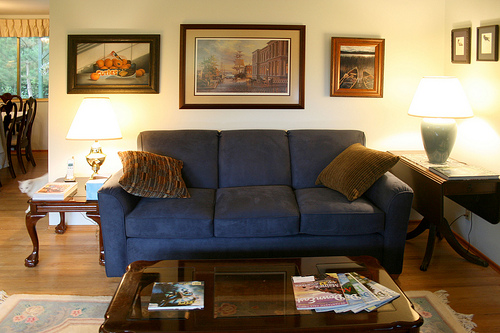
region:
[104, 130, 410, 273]
a dark blue couch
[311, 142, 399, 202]
a large brown pillow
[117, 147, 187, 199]
a large brown pillow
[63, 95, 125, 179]
a lit table lamp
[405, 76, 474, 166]
a lit table lamp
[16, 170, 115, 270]
a wooden end table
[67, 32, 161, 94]
a framed art print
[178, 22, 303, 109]
a framed art print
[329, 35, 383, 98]
a framed art print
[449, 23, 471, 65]
a framed art print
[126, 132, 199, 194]
The pillow on the left side of the sofa.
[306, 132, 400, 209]
The pillow on the right side of the sofa.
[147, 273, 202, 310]
The magazine on the left side of the center table.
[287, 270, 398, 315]
The magazines on the right side of the center table.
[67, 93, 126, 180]
The lamp on the small side table.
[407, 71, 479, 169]
The lamp on the long side table.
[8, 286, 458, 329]
The rug the center table is placed on.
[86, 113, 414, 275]
The blue sofa in the center of the room.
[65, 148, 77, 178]
The bottle of water on the small side table.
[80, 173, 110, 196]
The small blue box on the small side table.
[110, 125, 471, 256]
Blue couch against the wall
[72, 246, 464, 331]
Table with glass top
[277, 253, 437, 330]
Magazines on top of table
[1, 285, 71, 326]
Rug underneath the table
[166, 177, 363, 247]
Cushions on the couch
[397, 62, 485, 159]
Lamp sitting on the table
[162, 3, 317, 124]
Art piece on the wall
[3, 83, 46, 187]
Table surrounded by chairs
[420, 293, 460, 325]
Fringe on the carpet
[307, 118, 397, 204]
Brown pillow on the couch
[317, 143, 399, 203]
Brown throw pillow on a blue couch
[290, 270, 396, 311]
Magazines on the coffee table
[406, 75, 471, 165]
Table lamp on an end table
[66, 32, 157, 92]
Picture of fruit hanging on the wall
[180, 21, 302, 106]
Picture hung on the wall above the couch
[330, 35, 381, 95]
Picture with a wooden frame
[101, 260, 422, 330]
Coffee table in the living room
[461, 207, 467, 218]
Lamp plugged into electrical receptacle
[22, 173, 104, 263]
End table sitting beside a couch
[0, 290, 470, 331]
Area rug on the living room floor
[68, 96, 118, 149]
the light is on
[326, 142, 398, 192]
the pillow is brown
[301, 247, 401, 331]
magazinesa re on the table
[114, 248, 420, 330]
the table has glass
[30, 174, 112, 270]
the stool is wooden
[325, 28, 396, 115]
the frame is wooden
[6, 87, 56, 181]
chairs are in the background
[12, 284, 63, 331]
the floor is carpeted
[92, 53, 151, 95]
oranges are in the picture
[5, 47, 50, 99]
trees are in the background